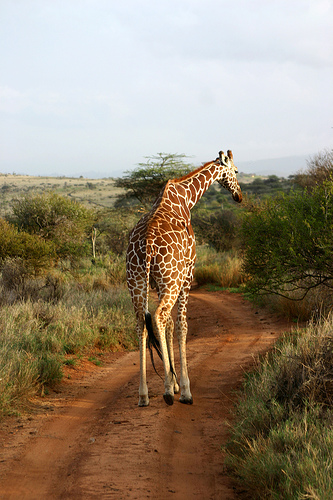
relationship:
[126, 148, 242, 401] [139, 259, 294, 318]
giraffe walking down a road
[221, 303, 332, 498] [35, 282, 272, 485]
dry grass beside road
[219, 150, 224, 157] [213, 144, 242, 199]
horn on head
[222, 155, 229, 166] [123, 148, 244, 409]
ear of a giraffe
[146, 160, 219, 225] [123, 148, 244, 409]
mane of a giraffe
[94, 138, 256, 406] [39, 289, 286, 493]
giraffe on a road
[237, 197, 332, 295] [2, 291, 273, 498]
tree by road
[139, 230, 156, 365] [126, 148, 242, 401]
tail of giraffe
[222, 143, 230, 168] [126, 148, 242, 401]
ear of a giraffe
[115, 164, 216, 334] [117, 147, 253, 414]
coat of a animal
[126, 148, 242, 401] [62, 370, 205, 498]
giraffe on dirt road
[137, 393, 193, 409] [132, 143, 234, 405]
hooves of giraffe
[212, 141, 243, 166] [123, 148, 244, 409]
horn on giraffe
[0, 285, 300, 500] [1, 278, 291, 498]
dirt road made of dirt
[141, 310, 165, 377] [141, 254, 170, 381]
tip of tail